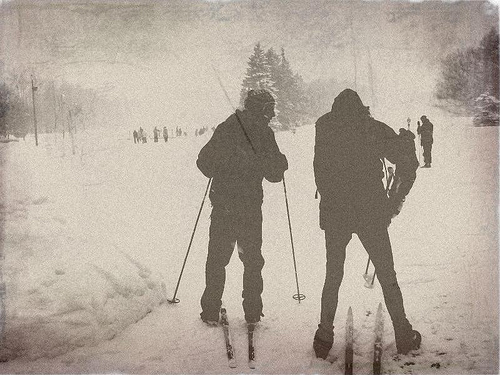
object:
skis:
[342, 298, 360, 374]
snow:
[410, 246, 497, 374]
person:
[302, 83, 434, 359]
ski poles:
[356, 253, 372, 281]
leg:
[309, 232, 356, 357]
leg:
[362, 228, 425, 356]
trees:
[235, 40, 284, 131]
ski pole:
[159, 176, 214, 313]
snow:
[5, 47, 226, 374]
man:
[414, 113, 437, 171]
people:
[160, 126, 171, 143]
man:
[169, 83, 297, 336]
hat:
[243, 88, 276, 119]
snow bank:
[3, 164, 172, 364]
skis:
[218, 297, 239, 374]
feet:
[238, 291, 267, 326]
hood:
[329, 88, 365, 118]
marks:
[429, 312, 496, 374]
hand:
[207, 166, 215, 174]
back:
[311, 114, 392, 233]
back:
[211, 114, 266, 236]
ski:
[380, 164, 403, 209]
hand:
[392, 196, 408, 219]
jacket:
[312, 113, 416, 234]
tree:
[472, 28, 499, 128]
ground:
[66, 159, 497, 374]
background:
[14, 70, 215, 154]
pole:
[26, 75, 51, 149]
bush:
[465, 94, 498, 128]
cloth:
[418, 123, 434, 146]